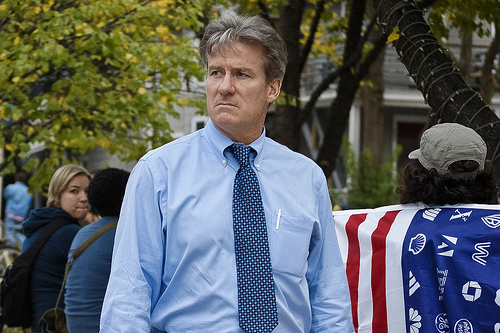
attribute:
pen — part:
[268, 203, 289, 233]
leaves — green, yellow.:
[3, 0, 158, 92]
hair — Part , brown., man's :
[257, 15, 284, 79]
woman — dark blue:
[0, 202, 83, 318]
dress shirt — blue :
[97, 114, 359, 331]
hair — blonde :
[44, 162, 94, 205]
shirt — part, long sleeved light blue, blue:
[97, 120, 358, 331]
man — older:
[376, 114, 493, 202]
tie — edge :
[224, 141, 282, 332]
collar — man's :
[202, 116, 271, 171]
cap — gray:
[408, 121, 485, 179]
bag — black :
[14, 187, 114, 311]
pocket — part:
[269, 212, 313, 280]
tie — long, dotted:
[228, 141, 280, 331]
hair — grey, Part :
[214, 13, 250, 36]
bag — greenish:
[40, 219, 119, 333]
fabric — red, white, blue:
[332, 203, 499, 333]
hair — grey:
[199, 12, 286, 73]